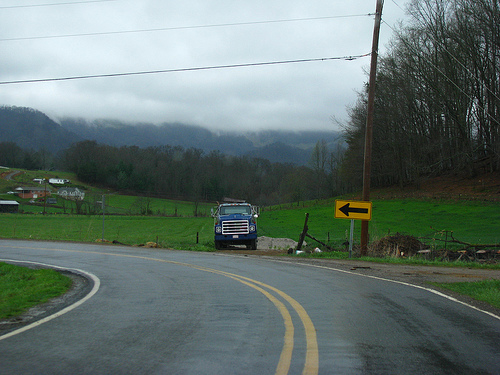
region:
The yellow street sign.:
[337, 200, 371, 217]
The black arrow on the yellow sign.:
[336, 203, 371, 217]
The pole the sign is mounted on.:
[347, 218, 355, 252]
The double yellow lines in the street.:
[6, 238, 319, 374]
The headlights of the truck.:
[210, 228, 253, 235]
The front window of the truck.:
[215, 205, 251, 212]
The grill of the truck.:
[220, 218, 248, 233]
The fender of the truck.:
[217, 234, 256, 240]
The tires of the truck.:
[215, 236, 259, 250]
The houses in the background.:
[2, 163, 83, 218]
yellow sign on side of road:
[335, 198, 372, 219]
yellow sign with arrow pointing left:
[335, 201, 370, 222]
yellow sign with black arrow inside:
[332, 199, 370, 217]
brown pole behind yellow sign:
[355, 0, 385, 257]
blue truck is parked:
[208, 198, 258, 251]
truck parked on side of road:
[209, 199, 260, 250]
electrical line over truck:
[0, 48, 374, 85]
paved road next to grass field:
[0, 204, 497, 246]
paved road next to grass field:
[0, 261, 70, 331]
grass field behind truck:
[0, 200, 496, 247]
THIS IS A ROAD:
[135, 302, 152, 342]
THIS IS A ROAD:
[366, 268, 408, 346]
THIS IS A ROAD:
[201, 275, 263, 355]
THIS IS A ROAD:
[167, 311, 311, 325]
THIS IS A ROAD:
[115, 244, 145, 273]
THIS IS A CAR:
[218, 199, 258, 253]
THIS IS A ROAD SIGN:
[341, 187, 371, 226]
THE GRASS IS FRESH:
[15, 275, 40, 297]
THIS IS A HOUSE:
[0, 195, 17, 206]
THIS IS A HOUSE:
[19, 182, 52, 204]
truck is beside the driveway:
[214, 177, 280, 237]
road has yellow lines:
[248, 267, 299, 372]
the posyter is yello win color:
[338, 197, 379, 228]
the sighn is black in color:
[328, 197, 379, 222]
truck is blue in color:
[201, 204, 251, 251]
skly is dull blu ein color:
[99, 71, 176, 121]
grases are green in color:
[133, 210, 182, 243]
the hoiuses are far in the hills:
[22, 160, 85, 194]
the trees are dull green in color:
[236, 153, 317, 186]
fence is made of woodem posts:
[289, 227, 352, 243]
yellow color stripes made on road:
[261, 284, 322, 373]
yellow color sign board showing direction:
[333, 201, 369, 219]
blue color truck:
[216, 204, 256, 251]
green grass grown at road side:
[3, 263, 48, 304]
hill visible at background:
[15, 107, 57, 151]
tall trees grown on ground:
[387, 53, 476, 180]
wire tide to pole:
[363, 0, 385, 205]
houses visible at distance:
[17, 185, 47, 200]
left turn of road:
[4, 242, 141, 294]